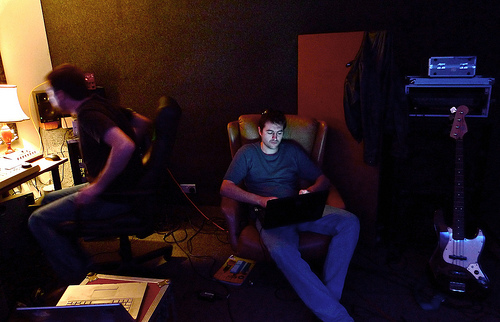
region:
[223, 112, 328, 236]
sitting man working on laptop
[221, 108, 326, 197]
man wearing dark blue short sleeved shirt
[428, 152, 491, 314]
partially shadowed upright electric guitar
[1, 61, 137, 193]
one man sitting in front of lamp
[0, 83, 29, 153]
one illuminated lamp with white shade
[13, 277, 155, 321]
one open silver laptop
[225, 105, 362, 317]
sitting man wearing blue jeans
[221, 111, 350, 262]
man sitting in brown leather chair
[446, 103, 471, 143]
top of one electric guitar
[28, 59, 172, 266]
one man sitting in dark office chair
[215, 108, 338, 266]
leather chair in room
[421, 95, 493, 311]
guitar upright in room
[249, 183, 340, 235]
open black laptop in man's lap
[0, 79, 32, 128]
white lampshade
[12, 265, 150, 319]
silver laptop on metal chest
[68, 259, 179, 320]
red and silver metal chest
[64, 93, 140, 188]
black short sleeve shirt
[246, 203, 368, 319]
pair of long pants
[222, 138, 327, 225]
blue short sleeve shirt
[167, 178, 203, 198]
white wall outlet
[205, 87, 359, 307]
man sitting on a chair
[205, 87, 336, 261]
man sitting on a chair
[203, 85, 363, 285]
man sitting on a chair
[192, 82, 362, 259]
man sitting on a chair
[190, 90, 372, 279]
man sitting on a chair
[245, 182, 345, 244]
the laptop is black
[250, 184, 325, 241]
the laptop is black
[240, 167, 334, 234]
the laptop is black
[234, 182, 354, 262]
the laptop is black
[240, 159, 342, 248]
the laptop is black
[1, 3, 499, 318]
Two men in a room.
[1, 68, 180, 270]
Man is at a desk.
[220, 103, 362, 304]
Man is sitting in a lounge chair.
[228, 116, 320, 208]
Light shining on the man.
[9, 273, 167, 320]
Computer on a box.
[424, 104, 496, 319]
Guitar leaning against a box.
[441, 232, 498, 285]
White on the guitar.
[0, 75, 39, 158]
Light on the desk.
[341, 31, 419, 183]
Coat on a door.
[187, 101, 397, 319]
a man sitting in a chair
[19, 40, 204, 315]
a man sitting on a computer chair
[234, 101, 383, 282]
a man on a laptop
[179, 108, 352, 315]
a man looking at a laptop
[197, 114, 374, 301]
a laptop on a lapt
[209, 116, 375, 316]
a laptop on a man's lap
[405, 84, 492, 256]
a guitar standin gup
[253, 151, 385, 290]
a black laptop open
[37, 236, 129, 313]
a silver laptop open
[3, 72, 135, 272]
a lamp on a table